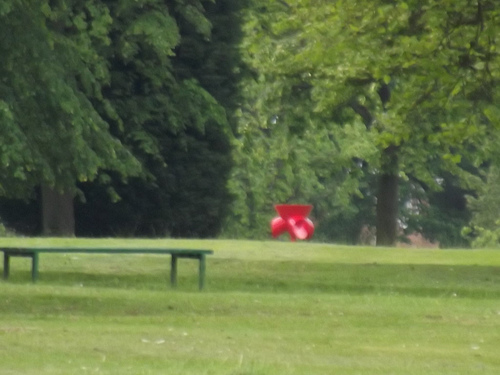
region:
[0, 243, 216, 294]
Bench on the grass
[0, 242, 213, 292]
Green bench on the grass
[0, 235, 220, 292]
Bench on the lawn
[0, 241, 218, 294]
Green bench on the lawn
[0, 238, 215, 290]
Bench has four legs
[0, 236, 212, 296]
Green bench has four legs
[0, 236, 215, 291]
Bench is the color green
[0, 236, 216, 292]
Bench is the color light green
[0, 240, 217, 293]
Bench is green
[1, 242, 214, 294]
Bench is dark green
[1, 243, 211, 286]
a bench in a field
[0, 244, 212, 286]
a bench with four legs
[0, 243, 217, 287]
a flat bench with no arm rests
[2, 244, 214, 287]
a flat bench with no back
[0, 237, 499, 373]
a field of grass with a bench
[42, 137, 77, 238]
the trunk of a large tree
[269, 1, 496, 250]
a tree with lighter green leaves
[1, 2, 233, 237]
a tree with darker green leaves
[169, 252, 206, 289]
the two right legs of the bench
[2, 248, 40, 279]
the two left legs of a bench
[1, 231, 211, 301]
Green bench in the grass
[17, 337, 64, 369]
Patch of green grass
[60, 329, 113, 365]
Patch of green grass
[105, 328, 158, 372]
Patch of green grass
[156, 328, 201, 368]
Patch of green grass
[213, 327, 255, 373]
Patch of green grass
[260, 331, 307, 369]
Patch of green grass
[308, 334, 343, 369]
Patch of green grass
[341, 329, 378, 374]
Patch of green grass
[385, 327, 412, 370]
Patch of green grass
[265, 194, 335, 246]
There is a lone red object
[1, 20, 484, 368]
Everything is green except one thing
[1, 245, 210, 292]
the bench is green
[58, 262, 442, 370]
The field is full of grass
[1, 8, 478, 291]
There are very tall trees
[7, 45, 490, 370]
the field has no people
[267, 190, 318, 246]
This is a basketball toy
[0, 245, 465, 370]
The grass is all healthy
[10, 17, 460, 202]
The trees are all healthy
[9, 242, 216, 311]
The bench holds nobody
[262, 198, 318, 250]
red slide in park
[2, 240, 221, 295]
green bench in park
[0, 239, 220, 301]
long bench on grass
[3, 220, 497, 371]
large green grassy field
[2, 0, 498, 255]
grove of green trees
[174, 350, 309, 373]
tops of weeds in foreground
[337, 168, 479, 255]
brown building beyond trees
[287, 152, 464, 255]
building behind tree on right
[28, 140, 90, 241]
large brown tree trunk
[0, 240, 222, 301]
long green park bench